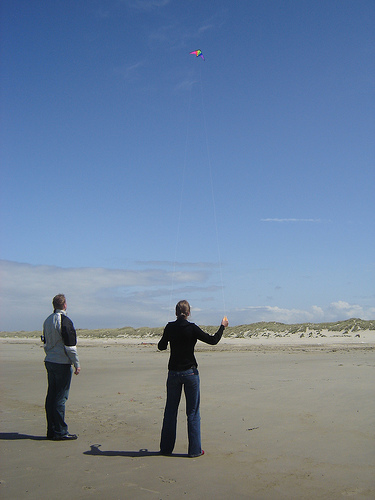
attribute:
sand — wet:
[1, 332, 372, 499]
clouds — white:
[0, 258, 373, 332]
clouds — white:
[256, 215, 322, 224]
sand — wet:
[254, 362, 350, 462]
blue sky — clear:
[248, 55, 344, 199]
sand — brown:
[209, 352, 370, 498]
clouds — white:
[0, 245, 373, 328]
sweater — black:
[157, 317, 225, 371]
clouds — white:
[205, 79, 275, 137]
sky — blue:
[1, 1, 372, 326]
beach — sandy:
[232, 362, 356, 424]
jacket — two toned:
[44, 311, 76, 360]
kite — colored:
[190, 48, 207, 63]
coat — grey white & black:
[39, 307, 80, 366]